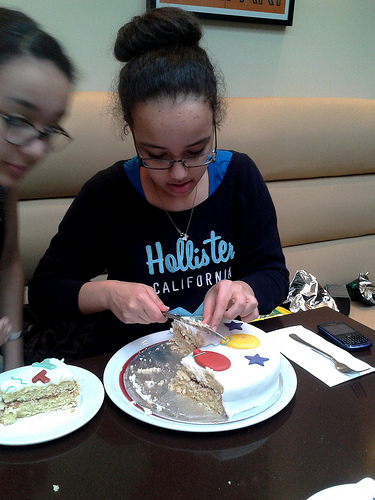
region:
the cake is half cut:
[174, 313, 282, 417]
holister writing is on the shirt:
[151, 231, 250, 281]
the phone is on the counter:
[324, 318, 372, 356]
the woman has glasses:
[0, 39, 80, 179]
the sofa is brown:
[276, 88, 373, 270]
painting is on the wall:
[149, 3, 294, 35]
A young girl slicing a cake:
[23, 3, 314, 453]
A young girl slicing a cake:
[23, 2, 303, 446]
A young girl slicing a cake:
[19, 4, 304, 439]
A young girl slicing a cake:
[15, 3, 306, 442]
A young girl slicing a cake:
[9, 3, 304, 437]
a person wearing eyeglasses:
[128, 128, 229, 176]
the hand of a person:
[110, 276, 162, 325]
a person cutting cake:
[102, 280, 284, 432]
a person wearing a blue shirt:
[124, 155, 234, 198]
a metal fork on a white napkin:
[282, 326, 367, 398]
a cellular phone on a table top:
[316, 315, 370, 355]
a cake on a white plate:
[108, 325, 298, 425]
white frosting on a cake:
[214, 377, 279, 406]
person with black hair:
[111, 15, 229, 104]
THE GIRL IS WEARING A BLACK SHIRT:
[30, 143, 302, 344]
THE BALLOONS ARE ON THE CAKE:
[199, 330, 259, 376]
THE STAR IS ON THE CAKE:
[243, 350, 270, 370]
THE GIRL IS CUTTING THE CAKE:
[139, 304, 286, 432]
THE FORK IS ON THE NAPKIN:
[285, 322, 368, 390]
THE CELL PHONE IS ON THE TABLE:
[318, 312, 370, 357]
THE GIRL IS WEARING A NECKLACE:
[144, 172, 212, 247]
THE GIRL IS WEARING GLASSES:
[118, 111, 223, 169]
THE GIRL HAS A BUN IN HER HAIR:
[103, 2, 236, 132]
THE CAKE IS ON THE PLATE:
[89, 320, 315, 449]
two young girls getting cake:
[16, 7, 278, 294]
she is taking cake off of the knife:
[92, 106, 296, 387]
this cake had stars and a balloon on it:
[154, 308, 277, 409]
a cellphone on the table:
[313, 315, 374, 357]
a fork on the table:
[283, 329, 373, 390]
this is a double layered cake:
[0, 359, 99, 443]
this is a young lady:
[112, 59, 245, 271]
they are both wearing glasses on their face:
[2, 63, 243, 213]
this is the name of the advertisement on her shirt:
[130, 234, 260, 318]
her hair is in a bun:
[97, 10, 232, 115]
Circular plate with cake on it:
[100, 315, 297, 438]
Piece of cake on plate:
[1, 355, 107, 447]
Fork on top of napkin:
[285, 329, 370, 378]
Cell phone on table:
[316, 317, 372, 352]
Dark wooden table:
[1, 306, 372, 498]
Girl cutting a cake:
[27, 7, 289, 339]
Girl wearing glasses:
[0, 3, 82, 369]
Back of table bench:
[1, 87, 373, 329]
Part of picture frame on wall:
[143, 1, 300, 28]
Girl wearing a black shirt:
[26, 10, 291, 340]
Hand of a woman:
[203, 274, 263, 339]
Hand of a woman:
[107, 275, 177, 330]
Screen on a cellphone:
[323, 322, 351, 335]